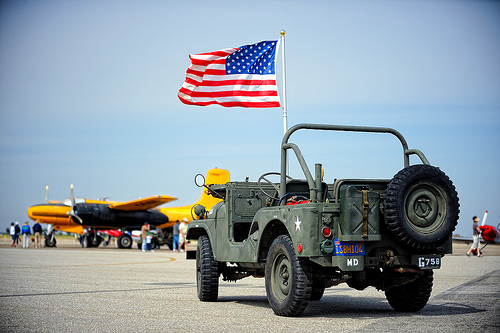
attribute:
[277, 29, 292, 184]
pole — silver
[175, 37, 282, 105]
flag — American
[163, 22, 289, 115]
flag — American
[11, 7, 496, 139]
sky — clear, blue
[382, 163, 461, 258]
tire — black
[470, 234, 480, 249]
pants — white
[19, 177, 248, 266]
airplane — yellow, black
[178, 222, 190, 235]
shirt — white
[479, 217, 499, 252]
airplane — white, red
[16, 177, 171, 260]
airplane — yellow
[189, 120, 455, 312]
jeep — green, military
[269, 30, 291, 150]
flag pole — silver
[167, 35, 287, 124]
flag — blue, red, white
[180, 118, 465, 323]
jeep — vintage looking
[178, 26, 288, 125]
flag — USA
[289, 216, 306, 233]
star — white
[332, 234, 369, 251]
license plate — blue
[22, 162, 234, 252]
plane — yellow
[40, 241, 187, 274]
line — yellow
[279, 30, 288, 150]
pole — silver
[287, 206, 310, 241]
design — star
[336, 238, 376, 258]
plate — blue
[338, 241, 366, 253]
lettering — yellow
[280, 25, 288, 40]
ball — decorative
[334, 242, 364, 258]
license plate — blue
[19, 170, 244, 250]
plane — yellow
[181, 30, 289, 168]
flag — American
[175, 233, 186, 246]
pants — khaki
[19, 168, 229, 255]
airplane — yellow, black